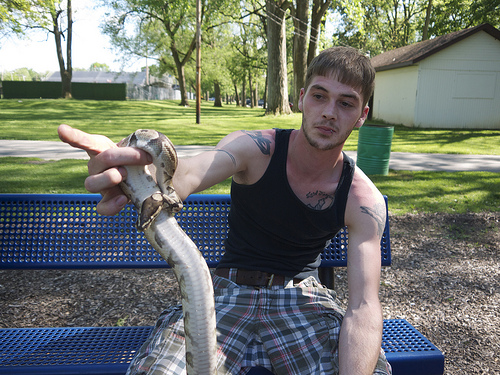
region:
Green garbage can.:
[355, 118, 392, 178]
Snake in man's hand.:
[117, 124, 230, 371]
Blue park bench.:
[5, 186, 441, 368]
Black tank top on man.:
[224, 125, 359, 284]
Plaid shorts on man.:
[142, 277, 367, 374]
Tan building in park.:
[371, 25, 497, 134]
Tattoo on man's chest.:
[295, 180, 337, 216]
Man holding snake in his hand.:
[80, 48, 383, 365]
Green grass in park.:
[15, 98, 296, 143]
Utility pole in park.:
[192, 5, 209, 125]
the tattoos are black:
[206, 133, 273, 173]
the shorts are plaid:
[212, 300, 344, 373]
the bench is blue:
[1, 329, 139, 366]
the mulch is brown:
[397, 217, 484, 336]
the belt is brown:
[237, 269, 299, 289]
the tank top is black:
[237, 132, 349, 277]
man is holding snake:
[89, 60, 385, 357]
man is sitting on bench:
[70, 62, 415, 373]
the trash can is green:
[359, 117, 401, 177]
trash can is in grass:
[355, 118, 432, 201]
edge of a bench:
[413, 353, 431, 367]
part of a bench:
[71, 345, 103, 370]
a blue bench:
[52, 237, 66, 249]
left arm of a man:
[355, 225, 377, 303]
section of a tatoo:
[259, 135, 264, 142]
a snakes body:
[195, 307, 200, 321]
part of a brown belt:
[254, 270, 261, 280]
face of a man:
[307, 110, 349, 143]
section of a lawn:
[442, 165, 464, 192]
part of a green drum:
[372, 138, 382, 155]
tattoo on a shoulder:
[237, 121, 279, 161]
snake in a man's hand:
[109, 121, 240, 374]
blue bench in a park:
[4, 181, 108, 373]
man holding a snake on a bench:
[50, 28, 437, 373]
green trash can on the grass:
[356, 116, 406, 184]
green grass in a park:
[14, 97, 189, 122]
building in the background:
[372, 13, 497, 139]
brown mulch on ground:
[432, 219, 498, 360]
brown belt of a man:
[211, 263, 329, 295]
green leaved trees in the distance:
[143, 1, 441, 29]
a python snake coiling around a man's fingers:
[115, 135, 184, 207]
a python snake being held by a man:
[63, 115, 260, 368]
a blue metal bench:
[13, 185, 148, 363]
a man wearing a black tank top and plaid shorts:
[217, 32, 377, 350]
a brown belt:
[225, 262, 310, 288]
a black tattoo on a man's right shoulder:
[243, 132, 276, 152]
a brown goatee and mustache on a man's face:
[301, 110, 342, 152]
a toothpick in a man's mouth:
[325, 125, 336, 136]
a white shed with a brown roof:
[360, 32, 497, 107]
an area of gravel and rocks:
[407, 226, 487, 318]